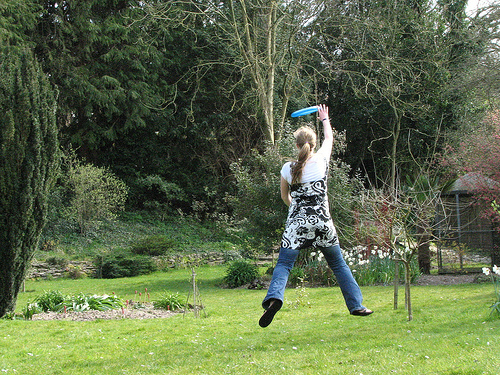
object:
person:
[257, 102, 375, 329]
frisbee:
[289, 103, 321, 120]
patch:
[218, 239, 421, 289]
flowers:
[305, 240, 412, 265]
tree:
[2, 2, 62, 318]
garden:
[0, 230, 499, 374]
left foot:
[257, 298, 283, 329]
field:
[1, 188, 500, 374]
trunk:
[404, 266, 417, 320]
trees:
[333, 159, 469, 323]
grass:
[3, 208, 500, 374]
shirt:
[279, 140, 344, 184]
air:
[2, 0, 500, 375]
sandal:
[352, 308, 376, 318]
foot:
[351, 303, 379, 319]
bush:
[220, 259, 259, 289]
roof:
[439, 168, 500, 194]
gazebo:
[437, 170, 500, 273]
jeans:
[260, 244, 368, 315]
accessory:
[322, 116, 331, 121]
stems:
[491, 274, 500, 310]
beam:
[416, 202, 432, 276]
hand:
[314, 102, 330, 122]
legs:
[313, 243, 364, 307]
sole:
[258, 299, 283, 329]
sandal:
[256, 299, 284, 329]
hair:
[289, 126, 319, 187]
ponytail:
[290, 142, 313, 190]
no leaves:
[350, 194, 402, 244]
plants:
[26, 288, 121, 313]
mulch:
[35, 308, 166, 320]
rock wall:
[28, 247, 246, 280]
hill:
[31, 159, 250, 273]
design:
[281, 177, 338, 249]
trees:
[292, 0, 497, 271]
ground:
[3, 185, 498, 373]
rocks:
[419, 276, 477, 286]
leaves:
[362, 267, 416, 284]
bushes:
[99, 236, 172, 279]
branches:
[352, 188, 448, 253]